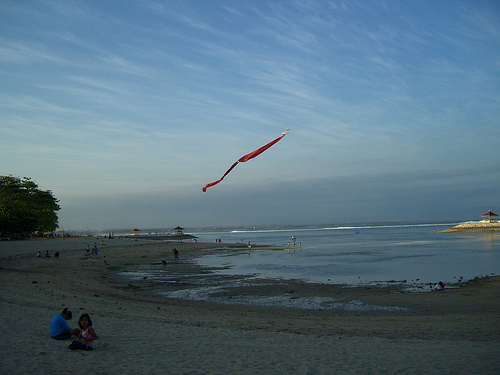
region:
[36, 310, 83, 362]
Person wearing blue shirt.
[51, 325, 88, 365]
Person wearing dark shorts.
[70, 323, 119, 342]
Person wearing pink shirt.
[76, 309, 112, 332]
Person has dark hair.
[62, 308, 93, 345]
Person has dark hair.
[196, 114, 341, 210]
Red kite flying in air.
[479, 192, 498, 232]
Umbrella sticking out of ground.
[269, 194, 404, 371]
Water near sandy beach.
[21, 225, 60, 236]
Green leaves on trees.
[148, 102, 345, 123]
Sky is blue with white wispy clouds.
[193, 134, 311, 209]
a big red kite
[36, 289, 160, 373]
people sitting on sand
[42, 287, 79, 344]
a man wearing blue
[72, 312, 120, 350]
a girl wearing pink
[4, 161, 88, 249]
big green trees on beach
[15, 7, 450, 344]
a very big beach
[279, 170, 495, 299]
a very big ocean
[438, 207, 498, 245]
a small island in the ocean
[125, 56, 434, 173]
big beautiful clouds in sky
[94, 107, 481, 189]
big clear blue sky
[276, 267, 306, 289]
edge of a shore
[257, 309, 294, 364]
part of a sandy beach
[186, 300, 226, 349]
part of sandy terrain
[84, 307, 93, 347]
a small girl on the beach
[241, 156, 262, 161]
a red kite in air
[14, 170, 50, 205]
branches of a tree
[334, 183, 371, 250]
part of the ocean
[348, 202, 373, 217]
section on the ocean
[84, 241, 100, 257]
group of people on the shore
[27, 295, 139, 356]
Two people sitting on the beach.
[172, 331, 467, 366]
Sand on the beach.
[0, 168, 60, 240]
A tree near the beach.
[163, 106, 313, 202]
A kite in the sky.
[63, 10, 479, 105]
The sky has wispy clouds in it.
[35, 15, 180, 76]
Part of the sky is blue.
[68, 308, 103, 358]
A girl on the beach is wearing pink.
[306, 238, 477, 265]
Water in the ocean.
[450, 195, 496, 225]
A red umbrella in the distance.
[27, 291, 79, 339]
The girl is wearing a blue shirt.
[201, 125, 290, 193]
a red kite in the air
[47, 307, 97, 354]
kids on the sand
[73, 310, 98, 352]
a young girl looking at the camera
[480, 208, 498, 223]
a pavilion on the peninsula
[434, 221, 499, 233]
a small peninsula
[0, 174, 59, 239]
a group of trees next to the sand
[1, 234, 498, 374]
a sandy beach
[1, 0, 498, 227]
a dark blue sky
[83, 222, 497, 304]
a dark body of water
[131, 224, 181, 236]
two pagodas next to each other